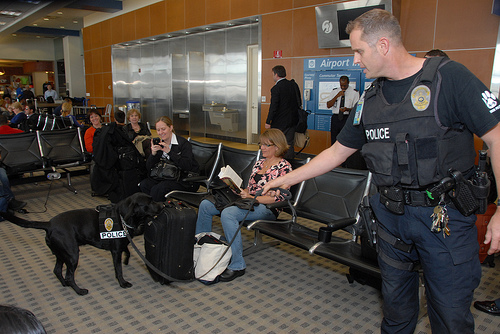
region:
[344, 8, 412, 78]
a man with graying hair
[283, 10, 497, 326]
a police officer in uniform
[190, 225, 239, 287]
a white canvas tote bag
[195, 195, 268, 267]
a person wearing blue jeans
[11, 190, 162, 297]
a black Labrador police dog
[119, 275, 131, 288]
the paw of a dog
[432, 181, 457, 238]
a collection of keys on a belt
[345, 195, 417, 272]
a police officer's gun in a thigh holster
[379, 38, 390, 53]
the ear of a person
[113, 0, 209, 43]
orange tiles on the wall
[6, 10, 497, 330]
a policeman with his dog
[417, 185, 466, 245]
keys on a belt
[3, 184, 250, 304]
black police dog at work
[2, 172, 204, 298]
a black police dog at work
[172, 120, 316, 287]
a woman in jeans reading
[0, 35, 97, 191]
people waiting in an airport lounge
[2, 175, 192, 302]
a working sniffer dog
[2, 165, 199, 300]
police dog sniffing baggage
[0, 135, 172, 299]
a police dog sniffing baggage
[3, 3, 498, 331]
a working dog and his master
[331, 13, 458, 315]
this is a man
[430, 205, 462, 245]
this is a bunch of key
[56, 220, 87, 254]
the dog is black in color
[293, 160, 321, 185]
the man is light skinned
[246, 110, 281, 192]
this is a lady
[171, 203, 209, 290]
this is a bag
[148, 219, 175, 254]
the bag is black in color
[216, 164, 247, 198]
this is a book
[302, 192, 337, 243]
this is a bench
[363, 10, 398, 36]
Man has short hair.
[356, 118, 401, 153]
White writing on man's vest.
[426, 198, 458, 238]
Keys hanging on man's belt.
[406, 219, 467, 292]
Man wearing blue pants.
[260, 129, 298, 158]
Woman has blonde hair.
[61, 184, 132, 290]
Black dog sniffing luggage.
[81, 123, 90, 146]
Person wearing red shirt.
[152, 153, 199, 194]
Person holding black bag.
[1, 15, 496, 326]
policeman with a black dog on a leash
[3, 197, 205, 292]
dog is sniffing a bag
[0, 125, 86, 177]
two empty seats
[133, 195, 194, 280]
woman's black bag in front of the woman in flower shirt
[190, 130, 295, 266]
woman is sitting down reading a book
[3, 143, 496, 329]
carpet has tiny blue squares in carpet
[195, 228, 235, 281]
white bag with stuff on the floor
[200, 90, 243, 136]
water fountain attached to the wall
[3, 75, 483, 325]
people waiting at an airport terminal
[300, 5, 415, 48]
a screen displaying updates about the planes